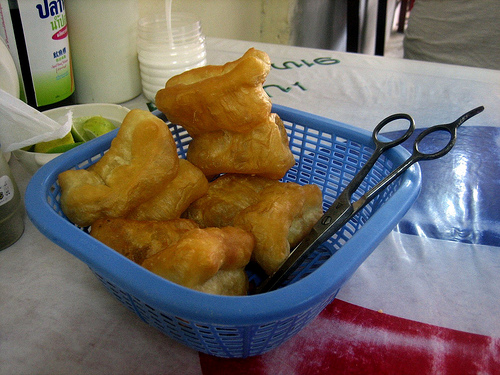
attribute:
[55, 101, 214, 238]
dough — fried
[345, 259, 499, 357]
cloth — red, white, blue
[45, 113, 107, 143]
limes — green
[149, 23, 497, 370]
tablecloth — red, white, blue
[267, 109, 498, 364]
circle — red, white, blue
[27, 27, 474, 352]
food — brown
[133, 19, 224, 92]
jar — glass, clear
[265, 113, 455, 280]
metal scissors — pair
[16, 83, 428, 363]
basket — blue, plastic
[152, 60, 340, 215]
doughnut — irregular, fried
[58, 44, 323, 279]
food — fried, golden brown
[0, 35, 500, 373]
tablecloth — blue, red, white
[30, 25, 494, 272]
table — white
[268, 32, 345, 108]
writing — green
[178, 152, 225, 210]
pastries — cooked, brown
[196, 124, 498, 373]
symbol — red, white, blue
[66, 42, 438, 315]
bowl — white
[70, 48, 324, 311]
dough — fried, plastic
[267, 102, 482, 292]
scissors — silver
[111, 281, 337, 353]
basket —  blue and plastic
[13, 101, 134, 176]
bowl — small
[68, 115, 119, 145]
slice — green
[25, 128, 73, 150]
slice — green